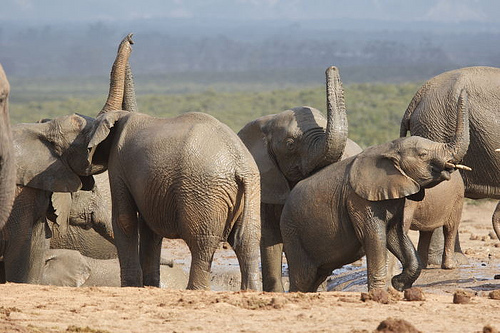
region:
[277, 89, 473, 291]
a small gray elephant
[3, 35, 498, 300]
a herd of gray elephants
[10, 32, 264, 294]
two elephants touching their trunks together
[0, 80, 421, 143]
green grassy flat field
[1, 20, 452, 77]
trees covered in fog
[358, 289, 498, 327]
brown rocks laying on the ground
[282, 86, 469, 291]
small elephant with two small tusks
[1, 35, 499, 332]
elephant playing in a mud hole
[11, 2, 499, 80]
hill behind the flat land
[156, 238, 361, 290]
muddy hole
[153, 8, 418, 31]
this is the sky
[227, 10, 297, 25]
the sky is blue in color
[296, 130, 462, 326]
this is a elephant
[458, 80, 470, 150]
this is the trunk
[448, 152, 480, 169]
this is the tusks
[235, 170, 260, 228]
this is the tail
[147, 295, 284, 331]
this is the ground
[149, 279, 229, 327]
the ground is brown in color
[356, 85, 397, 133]
this is a forest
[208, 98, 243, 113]
the leaves are green in color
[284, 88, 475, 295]
This is an elephant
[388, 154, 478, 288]
This is an elephant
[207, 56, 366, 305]
This is an elephant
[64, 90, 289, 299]
This is an elephant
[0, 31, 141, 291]
This is an elephant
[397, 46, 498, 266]
This is an elephant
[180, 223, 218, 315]
Leg of an elephant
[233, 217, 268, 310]
Leg of an elephant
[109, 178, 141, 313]
Leg of an elephant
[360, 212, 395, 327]
Leg of an elephant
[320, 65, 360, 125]
trunk of the elephant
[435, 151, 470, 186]
tusk of the elephant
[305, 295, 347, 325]
dirt under the elephant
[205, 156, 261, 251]
tail of the elephant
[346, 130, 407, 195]
ear of the elephant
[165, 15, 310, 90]
hills in the background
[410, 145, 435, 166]
eye of the elephant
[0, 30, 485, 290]
many elephants grouped together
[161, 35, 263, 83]
many trees in the distance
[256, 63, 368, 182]
elephant with trunk raised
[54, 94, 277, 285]
a baby elephant in mud.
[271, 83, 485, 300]
a baby elephant standing in mud.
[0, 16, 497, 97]
foot hills in the distance.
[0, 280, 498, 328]
A dirt ground under elephant.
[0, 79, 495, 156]
A field of green grass.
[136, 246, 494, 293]
a puddle of water.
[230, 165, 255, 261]
a tail on an elephant.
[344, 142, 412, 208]
an ear on an elephant.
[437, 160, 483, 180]
a tusk on an elephant.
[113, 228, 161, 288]
a front left leg.